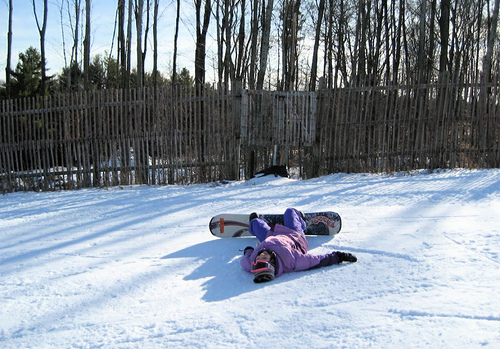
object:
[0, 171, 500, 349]
snow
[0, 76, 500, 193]
stick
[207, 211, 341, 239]
snowboard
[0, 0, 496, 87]
cloud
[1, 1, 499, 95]
blue sky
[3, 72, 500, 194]
fence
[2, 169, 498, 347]
hill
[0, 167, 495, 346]
hill side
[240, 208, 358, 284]
female